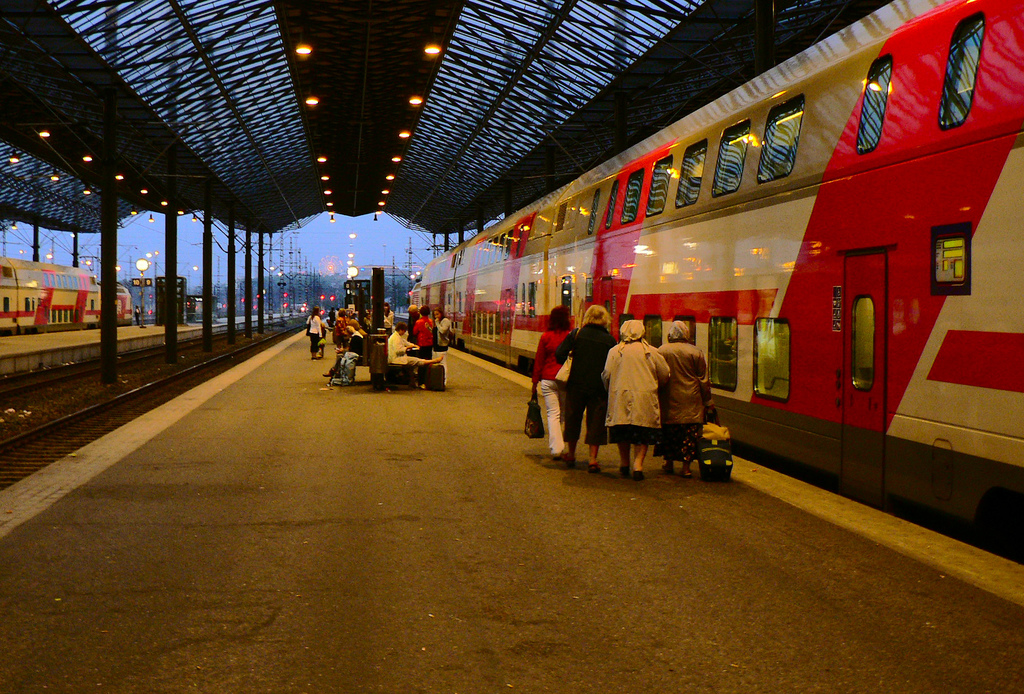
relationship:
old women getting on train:
[490, 284, 769, 490] [406, 33, 1016, 504]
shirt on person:
[303, 310, 332, 337] [295, 303, 341, 377]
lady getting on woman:
[657, 320, 715, 477] [529, 296, 581, 469]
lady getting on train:
[600, 319, 669, 480] [411, 7, 1016, 552]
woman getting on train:
[555, 301, 616, 476] [411, 7, 1016, 552]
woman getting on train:
[529, 296, 581, 469] [411, 7, 1016, 552]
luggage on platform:
[696, 413, 736, 487] [0, 310, 1024, 694]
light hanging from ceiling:
[302, 93, 324, 111] [279, 7, 468, 221]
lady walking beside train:
[648, 312, 711, 487] [411, 7, 1016, 552]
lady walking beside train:
[596, 309, 676, 493] [411, 7, 1016, 552]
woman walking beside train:
[555, 304, 618, 473] [411, 7, 1016, 552]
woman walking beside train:
[531, 305, 572, 461] [411, 7, 1016, 552]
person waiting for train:
[382, 320, 449, 372] [411, 7, 1016, 552]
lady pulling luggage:
[648, 312, 711, 487] [693, 385, 737, 487]